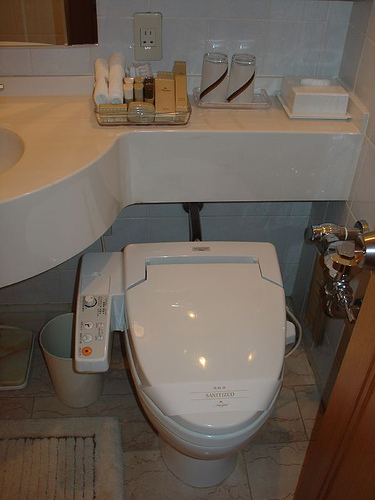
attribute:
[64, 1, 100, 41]
door — wooden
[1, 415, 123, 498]
edge of mat — thick, white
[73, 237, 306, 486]
part of toilet — white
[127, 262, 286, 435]
part of toilet seat — white, closed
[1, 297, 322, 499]
part of floor — cracked, made of marble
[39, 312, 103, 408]
trash can — beige colored, white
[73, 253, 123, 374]
white strip — made of chrome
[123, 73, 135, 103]
bottles of shampoo — small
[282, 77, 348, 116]
tissue box — white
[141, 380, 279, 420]
paper — white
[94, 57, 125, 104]
hand towels — white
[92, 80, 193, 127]
paper towel containe — white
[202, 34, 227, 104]
water glass — striped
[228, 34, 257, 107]
water glass — striped